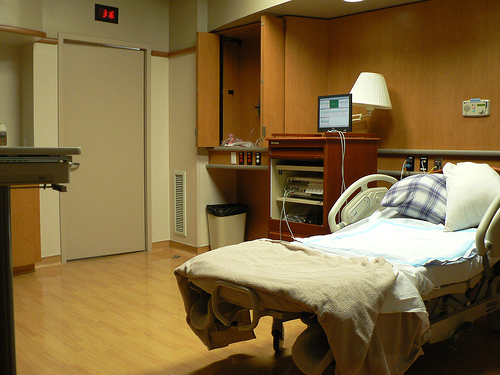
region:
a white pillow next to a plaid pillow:
[445, 161, 499, 230]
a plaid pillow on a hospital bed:
[381, 168, 450, 226]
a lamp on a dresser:
[346, 66, 396, 144]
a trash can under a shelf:
[197, 197, 247, 260]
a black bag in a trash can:
[206, 197, 248, 216]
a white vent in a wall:
[170, 171, 187, 239]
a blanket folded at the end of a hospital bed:
[172, 228, 411, 357]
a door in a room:
[45, 29, 162, 255]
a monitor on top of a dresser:
[307, 94, 367, 133]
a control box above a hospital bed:
[454, 93, 497, 119]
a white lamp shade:
[344, 67, 399, 115]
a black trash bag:
[203, 196, 250, 219]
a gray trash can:
[204, 199, 253, 251]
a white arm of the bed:
[320, 170, 400, 233]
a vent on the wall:
[167, 164, 187, 240]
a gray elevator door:
[55, 30, 156, 265]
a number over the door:
[90, 2, 123, 29]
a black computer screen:
[310, 91, 355, 138]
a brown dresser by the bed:
[259, 127, 386, 250]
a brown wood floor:
[8, 242, 311, 374]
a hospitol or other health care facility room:
[2, 2, 497, 368]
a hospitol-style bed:
[176, 155, 496, 366]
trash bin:
[196, 193, 249, 249]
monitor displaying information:
[310, 87, 355, 142]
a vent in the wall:
[165, 150, 195, 242]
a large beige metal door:
[47, 22, 153, 262]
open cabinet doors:
[190, 10, 281, 153]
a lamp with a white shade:
[315, 62, 395, 142]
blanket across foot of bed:
[170, 225, 440, 368]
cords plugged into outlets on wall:
[385, 145, 452, 178]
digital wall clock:
[90, 5, 122, 22]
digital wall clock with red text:
[94, 5, 126, 22]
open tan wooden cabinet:
[188, 18, 293, 165]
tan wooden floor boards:
[44, 267, 163, 372]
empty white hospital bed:
[340, 182, 485, 329]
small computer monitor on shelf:
[310, 92, 352, 139]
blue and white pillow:
[385, 171, 464, 221]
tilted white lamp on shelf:
[349, 67, 399, 142]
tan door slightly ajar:
[58, 30, 158, 267]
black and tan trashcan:
[202, 182, 244, 266]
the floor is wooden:
[153, 301, 165, 320]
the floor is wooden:
[126, 297, 152, 328]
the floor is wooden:
[51, 243, 104, 304]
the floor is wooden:
[143, 354, 169, 368]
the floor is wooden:
[148, 328, 178, 343]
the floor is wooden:
[131, 328, 160, 349]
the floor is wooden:
[96, 284, 129, 310]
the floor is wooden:
[112, 291, 132, 313]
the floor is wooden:
[163, 328, 183, 367]